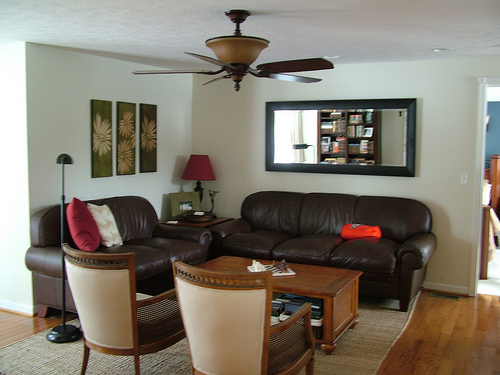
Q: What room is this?
A: Living room.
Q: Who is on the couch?
A: No one.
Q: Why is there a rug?
A: To decorate.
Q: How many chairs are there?
A: Two.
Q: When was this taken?
A: During the day.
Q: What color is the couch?
A: Brown.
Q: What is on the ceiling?
A: Fan.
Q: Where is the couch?
A: Against the wall.